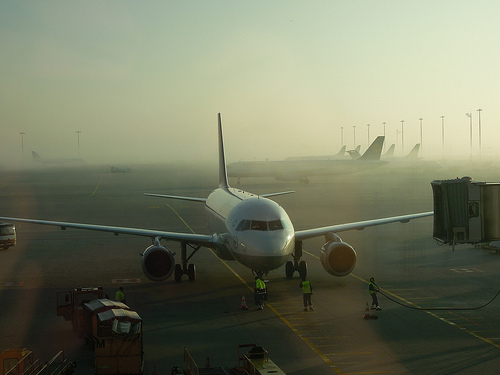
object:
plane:
[1, 108, 431, 287]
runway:
[157, 195, 496, 364]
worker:
[298, 277, 314, 310]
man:
[370, 270, 389, 323]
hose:
[379, 280, 495, 313]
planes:
[247, 148, 418, 188]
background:
[0, 0, 498, 175]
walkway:
[425, 170, 496, 256]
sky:
[0, 0, 498, 159]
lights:
[304, 89, 496, 137]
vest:
[299, 282, 318, 290]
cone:
[368, 300, 377, 337]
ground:
[404, 230, 456, 310]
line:
[267, 321, 336, 365]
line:
[423, 287, 483, 346]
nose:
[230, 238, 305, 269]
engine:
[308, 220, 364, 270]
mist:
[369, 55, 499, 116]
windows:
[265, 218, 285, 233]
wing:
[0, 214, 227, 256]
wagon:
[57, 280, 172, 359]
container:
[56, 267, 106, 306]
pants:
[302, 293, 313, 308]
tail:
[214, 110, 227, 186]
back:
[172, 353, 207, 367]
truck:
[174, 341, 291, 373]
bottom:
[239, 249, 301, 274]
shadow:
[128, 276, 268, 345]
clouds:
[283, 20, 325, 48]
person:
[250, 276, 268, 307]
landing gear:
[172, 260, 203, 291]